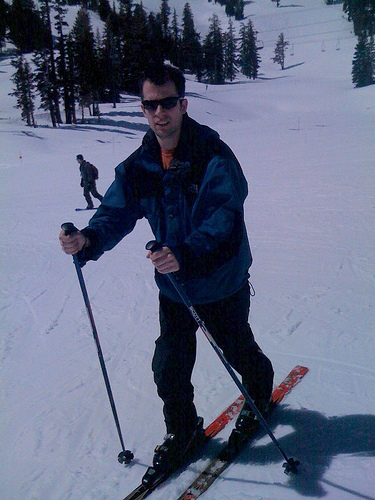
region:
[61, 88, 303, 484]
a person using snowboard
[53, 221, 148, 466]
a person holding ski-pole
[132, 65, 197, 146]
a person looking in to the camera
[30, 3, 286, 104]
pine trees in the snow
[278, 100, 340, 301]
a place with full of snow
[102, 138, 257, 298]
a man wearing blue color blanket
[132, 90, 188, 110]
a man wearing black color eyeglass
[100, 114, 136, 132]
shadow of the pine tree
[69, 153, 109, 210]
a person holding backbag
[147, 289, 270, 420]
a person wearing black color jean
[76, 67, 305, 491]
man skiing on a sunny day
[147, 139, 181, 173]
orange shirt being worn under the jacket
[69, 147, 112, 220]
person in the background walking to the left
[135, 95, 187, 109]
sunglasses on the mans face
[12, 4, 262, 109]
evergreen trees on the slope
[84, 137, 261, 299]
heavyweight blue jacket being worn by the man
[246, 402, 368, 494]
the mans shadow in the snow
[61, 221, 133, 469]
ski pole in the mans right hand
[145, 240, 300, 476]
ski pole in the mans left hand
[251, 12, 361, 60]
ski lift chairs traveling through the air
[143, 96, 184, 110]
sunglasses on a face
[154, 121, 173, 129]
teeth in a mouth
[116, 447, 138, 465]
disk grip on the ski pole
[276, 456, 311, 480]
disk grip on the ski pole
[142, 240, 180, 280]
a hand holding a ski pole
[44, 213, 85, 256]
a hand grasping a ski pole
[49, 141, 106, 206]
a man wearing a gray jacket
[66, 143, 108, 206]
a man carrying a backpack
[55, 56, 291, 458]
a man wearing black pants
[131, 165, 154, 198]
a black patch on a blue jacket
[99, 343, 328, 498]
The man is skiing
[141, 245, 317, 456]
holding ski poles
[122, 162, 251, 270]
the suit is blue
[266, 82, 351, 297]
The snow is white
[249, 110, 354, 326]
there is snow on the ground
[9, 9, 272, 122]
There are trees in the background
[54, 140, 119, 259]
Another person is here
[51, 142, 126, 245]
this person is snowboarding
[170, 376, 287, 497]
his skis are red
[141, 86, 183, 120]
he is wearing black goggles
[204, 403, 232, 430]
red color on ski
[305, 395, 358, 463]
man's shadow cast on the ground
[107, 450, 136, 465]
end of black ski pole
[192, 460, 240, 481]
snow on the ski pole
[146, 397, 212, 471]
black ski shoes on pole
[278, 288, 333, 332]
tracks in the snow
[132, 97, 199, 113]
goggles on man's face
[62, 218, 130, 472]
ski pole in man's hand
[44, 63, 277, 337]
skiers walking on the snow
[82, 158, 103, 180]
back pack on skier's back